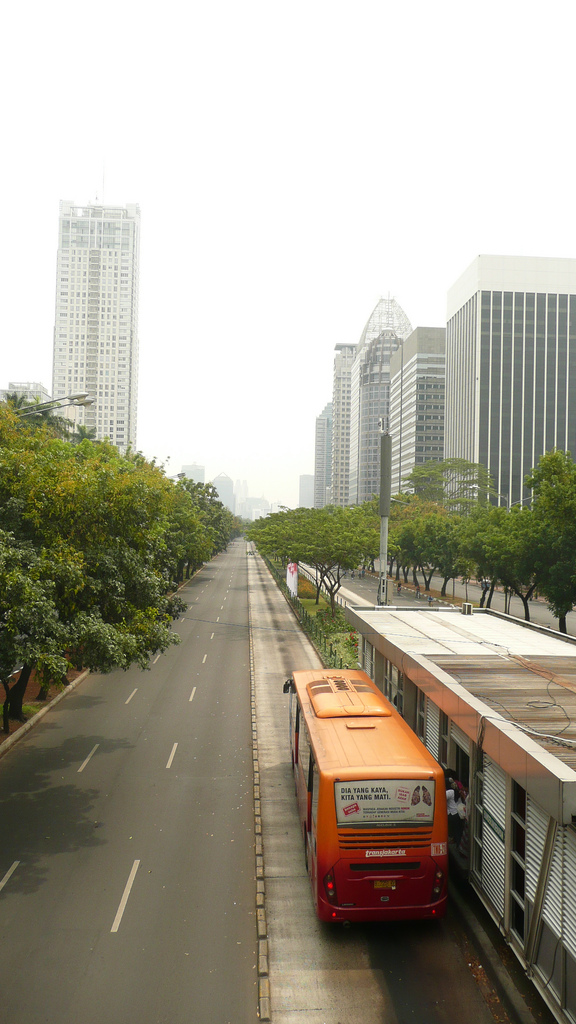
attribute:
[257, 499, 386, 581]
trees — young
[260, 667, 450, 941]
bus — orange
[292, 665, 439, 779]
roof — orange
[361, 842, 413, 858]
writing — white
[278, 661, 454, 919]
bus — orange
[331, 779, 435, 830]
ad — white 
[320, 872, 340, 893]
tail light — red 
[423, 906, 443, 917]
tail light — red 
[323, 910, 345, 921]
tail light — red 